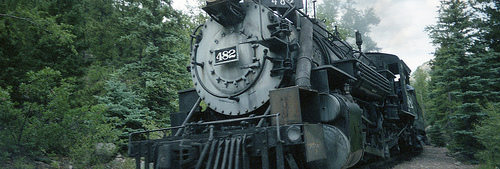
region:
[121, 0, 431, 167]
Black train in forest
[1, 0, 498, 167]
Forest train is going through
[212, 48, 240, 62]
Number plate on front of train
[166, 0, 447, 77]
Sky full of clouds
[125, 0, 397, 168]
Engine of train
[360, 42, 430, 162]
First car of train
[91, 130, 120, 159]
Gray rock in forest beside train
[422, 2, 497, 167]
Pine trees growing beside train track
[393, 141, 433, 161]
Black wheels of the train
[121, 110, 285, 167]
Front grate of train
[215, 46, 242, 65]
The number on the front of a train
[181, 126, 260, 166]
The front grill of a train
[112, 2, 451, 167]
A black steam train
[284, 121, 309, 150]
The headlight on a train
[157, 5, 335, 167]
The front of a train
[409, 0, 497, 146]
Tree's beside a train track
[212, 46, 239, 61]
The number 482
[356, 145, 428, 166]
The train track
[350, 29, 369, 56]
The train's whistle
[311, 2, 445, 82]
Hazy smoke from a train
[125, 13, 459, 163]
this is a train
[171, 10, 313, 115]
front grey part of train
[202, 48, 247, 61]
numbers on the front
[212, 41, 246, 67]
white numbers on train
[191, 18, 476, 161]
the train is black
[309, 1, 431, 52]
smoke coming from train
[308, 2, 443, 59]
train smoke is grey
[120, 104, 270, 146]
black rail on the train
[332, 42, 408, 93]
black side rails on train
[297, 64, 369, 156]
grey engine part on train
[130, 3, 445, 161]
a train in the area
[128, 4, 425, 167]
the train is black and gray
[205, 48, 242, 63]
numbers on the front of the train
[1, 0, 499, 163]
trees on the sides of the train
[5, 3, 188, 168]
the trees are a dark green color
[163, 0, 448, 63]
the sky is bright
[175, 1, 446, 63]
the sky is white in color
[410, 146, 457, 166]
dirt on the ground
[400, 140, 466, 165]
the dirt is a dark brown color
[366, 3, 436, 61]
clouds in the sky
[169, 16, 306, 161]
front of the train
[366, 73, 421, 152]
side of the train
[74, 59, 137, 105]
the trees are large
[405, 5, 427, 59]
clouds in the sky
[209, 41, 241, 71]
number of the train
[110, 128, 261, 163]
engine of the train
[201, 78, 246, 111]
the train is grey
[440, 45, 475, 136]
the trees are dense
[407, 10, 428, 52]
the sky is hazy